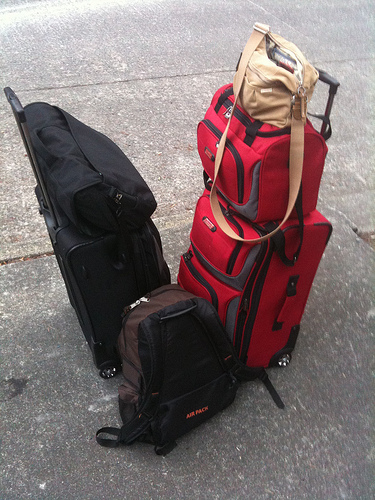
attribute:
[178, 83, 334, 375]
luggage — red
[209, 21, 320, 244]
purse — khaki, unzipped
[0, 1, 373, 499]
ground — gray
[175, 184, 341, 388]
bag — luggage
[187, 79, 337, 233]
bag — luggage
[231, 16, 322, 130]
bag — luggage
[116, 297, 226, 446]
bag — luggage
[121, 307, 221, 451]
backpack — brown and black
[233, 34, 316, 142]
purse — open, tan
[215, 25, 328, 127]
purse — tan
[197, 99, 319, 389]
luggage — red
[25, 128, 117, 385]
luggage — black, rolling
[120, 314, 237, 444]
backpack — brown and black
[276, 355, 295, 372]
wheel — luggage, rolling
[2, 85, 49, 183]
handle — rolling, black, luggage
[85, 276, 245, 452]
backpack — black and brown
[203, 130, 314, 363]
suitcase — red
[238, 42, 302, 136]
bag — tan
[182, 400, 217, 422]
logo — orange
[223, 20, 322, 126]
purse — tan, open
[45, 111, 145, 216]
bag — black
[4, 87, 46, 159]
handle — black, suitcase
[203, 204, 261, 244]
strap — brown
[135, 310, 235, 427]
bag — brown and black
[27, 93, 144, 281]
luggage — black